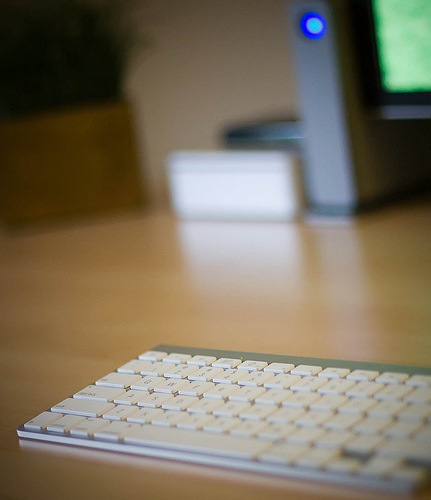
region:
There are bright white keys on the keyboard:
[264, 386, 284, 442]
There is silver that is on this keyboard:
[287, 353, 293, 367]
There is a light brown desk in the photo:
[267, 256, 284, 293]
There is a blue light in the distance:
[297, 10, 331, 50]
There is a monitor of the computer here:
[364, 37, 396, 76]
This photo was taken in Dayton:
[98, 258, 370, 459]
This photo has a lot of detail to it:
[57, 148, 278, 489]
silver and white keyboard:
[30, 306, 408, 485]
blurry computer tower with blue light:
[285, 11, 387, 224]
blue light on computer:
[297, 13, 329, 45]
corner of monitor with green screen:
[368, 8, 421, 134]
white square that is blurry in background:
[159, 140, 296, 230]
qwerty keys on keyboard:
[135, 369, 299, 407]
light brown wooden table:
[52, 249, 371, 346]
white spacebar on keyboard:
[131, 420, 268, 467]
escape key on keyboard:
[140, 339, 160, 367]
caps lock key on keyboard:
[69, 372, 145, 424]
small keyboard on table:
[105, 343, 426, 496]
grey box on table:
[273, 19, 388, 219]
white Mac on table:
[148, 120, 299, 223]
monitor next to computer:
[342, 6, 428, 77]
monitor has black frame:
[360, 0, 417, 114]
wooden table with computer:
[76, 220, 376, 359]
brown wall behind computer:
[159, 18, 250, 130]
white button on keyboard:
[142, 356, 167, 374]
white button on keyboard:
[189, 362, 216, 381]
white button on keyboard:
[213, 367, 243, 384]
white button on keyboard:
[240, 369, 269, 389]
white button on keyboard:
[267, 372, 296, 393]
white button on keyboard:
[47, 414, 82, 435]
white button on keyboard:
[92, 418, 132, 442]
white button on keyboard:
[15, 398, 59, 434]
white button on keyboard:
[47, 403, 77, 438]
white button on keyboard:
[72, 411, 105, 440]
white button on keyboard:
[96, 414, 133, 446]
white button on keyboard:
[119, 418, 271, 466]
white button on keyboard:
[257, 437, 300, 470]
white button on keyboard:
[296, 441, 334, 477]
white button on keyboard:
[326, 452, 362, 475]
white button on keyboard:
[132, 340, 164, 362]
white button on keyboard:
[161, 343, 189, 365]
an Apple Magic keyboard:
[15, 338, 427, 491]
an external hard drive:
[290, 0, 415, 218]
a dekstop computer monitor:
[347, 2, 427, 124]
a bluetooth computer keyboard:
[19, 342, 429, 499]